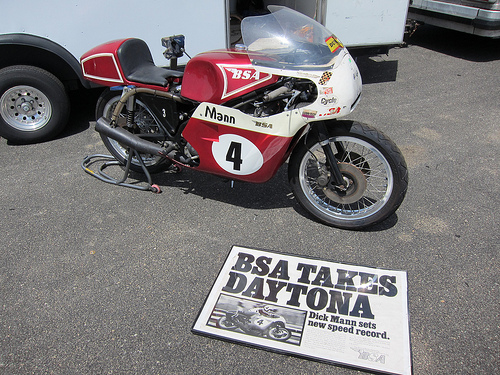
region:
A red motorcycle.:
[77, 3, 409, 232]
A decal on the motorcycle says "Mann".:
[203, 103, 238, 127]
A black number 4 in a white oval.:
[212, 132, 264, 177]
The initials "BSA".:
[215, 60, 273, 100]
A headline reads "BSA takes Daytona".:
[190, 244, 422, 374]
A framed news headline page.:
[190, 243, 420, 373]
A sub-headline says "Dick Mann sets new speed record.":
[305, 308, 394, 343]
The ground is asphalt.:
[10, 198, 180, 363]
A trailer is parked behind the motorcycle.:
[2, 0, 408, 144]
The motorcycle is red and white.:
[77, 3, 410, 233]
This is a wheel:
[287, 109, 415, 253]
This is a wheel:
[1, 63, 73, 158]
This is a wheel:
[91, 92, 173, 180]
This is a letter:
[232, 241, 253, 272]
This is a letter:
[252, 249, 270, 279]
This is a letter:
[292, 252, 320, 290]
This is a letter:
[314, 258, 338, 289]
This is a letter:
[331, 262, 361, 293]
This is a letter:
[354, 263, 382, 291]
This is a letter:
[377, 269, 401, 301]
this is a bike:
[34, 10, 446, 244]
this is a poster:
[205, 229, 453, 373]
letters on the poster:
[225, 245, 300, 272]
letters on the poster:
[290, 257, 366, 292]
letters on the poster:
[354, 254, 402, 297]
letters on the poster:
[313, 322, 345, 339]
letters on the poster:
[227, 275, 289, 307]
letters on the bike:
[196, 92, 251, 130]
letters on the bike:
[208, 65, 275, 92]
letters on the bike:
[237, 120, 279, 132]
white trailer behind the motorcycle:
[57, 12, 108, 54]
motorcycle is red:
[173, 101, 210, 174]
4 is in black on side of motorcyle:
[221, 128, 274, 188]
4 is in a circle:
[225, 131, 263, 176]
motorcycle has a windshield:
[265, 19, 314, 66]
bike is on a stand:
[98, 132, 154, 195]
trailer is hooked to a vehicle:
[394, 13, 471, 48]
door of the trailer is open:
[196, 14, 269, 40]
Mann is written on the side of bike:
[205, 103, 237, 131]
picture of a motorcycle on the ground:
[246, 296, 295, 354]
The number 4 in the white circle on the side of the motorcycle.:
[222, 137, 243, 168]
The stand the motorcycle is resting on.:
[103, 149, 152, 187]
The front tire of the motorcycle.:
[291, 117, 408, 230]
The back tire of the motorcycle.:
[95, 89, 175, 163]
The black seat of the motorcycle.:
[113, 42, 180, 91]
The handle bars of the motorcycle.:
[249, 76, 302, 103]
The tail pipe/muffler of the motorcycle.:
[87, 110, 171, 162]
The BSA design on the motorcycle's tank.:
[217, 60, 269, 94]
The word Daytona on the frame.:
[226, 270, 387, 335]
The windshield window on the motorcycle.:
[248, 5, 340, 67]